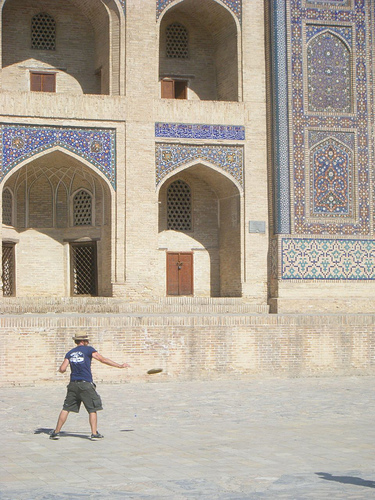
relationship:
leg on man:
[81, 411, 121, 449] [49, 331, 130, 439]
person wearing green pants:
[49, 327, 133, 443] [61, 380, 104, 415]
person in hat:
[49, 327, 133, 443] [71, 330, 88, 340]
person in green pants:
[32, 319, 133, 451] [61, 374, 104, 415]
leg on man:
[80, 385, 102, 434] [42, 327, 149, 441]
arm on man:
[88, 346, 130, 367] [49, 331, 130, 439]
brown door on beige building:
[163, 251, 195, 296] [0, 0, 374, 375]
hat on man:
[72, 330, 90, 343] [49, 331, 130, 439]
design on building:
[293, 271, 299, 276] [1, 1, 372, 392]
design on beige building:
[296, 256, 309, 271] [0, 0, 375, 387]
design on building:
[259, 226, 369, 288] [1, 1, 372, 392]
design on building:
[279, 231, 373, 279] [1, 1, 372, 392]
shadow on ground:
[119, 427, 136, 433] [0, 373, 375, 498]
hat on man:
[72, 330, 89, 338] [49, 331, 130, 439]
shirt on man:
[64, 345, 95, 378] [49, 331, 130, 439]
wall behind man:
[192, 309, 233, 351] [31, 279, 172, 438]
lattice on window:
[72, 241, 97, 298] [68, 238, 100, 295]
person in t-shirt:
[49, 327, 133, 443] [59, 341, 100, 384]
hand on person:
[120, 362, 133, 369] [49, 327, 133, 443]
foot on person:
[48, 423, 61, 440] [33, 329, 132, 440]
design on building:
[269, 0, 374, 280] [1, 1, 372, 392]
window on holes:
[164, 174, 195, 234] [173, 183, 187, 218]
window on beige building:
[164, 174, 195, 234] [0, 0, 375, 387]